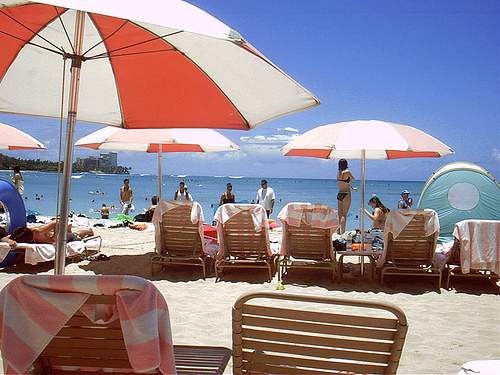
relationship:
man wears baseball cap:
[399, 190, 410, 213] [402, 187, 409, 194]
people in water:
[37, 190, 92, 207] [70, 198, 85, 208]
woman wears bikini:
[334, 157, 359, 234] [337, 169, 352, 201]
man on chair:
[395, 190, 412, 210] [0, 242, 100, 262]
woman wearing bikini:
[333, 160, 364, 230] [339, 189, 342, 199]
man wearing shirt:
[245, 173, 284, 237] [257, 186, 272, 210]